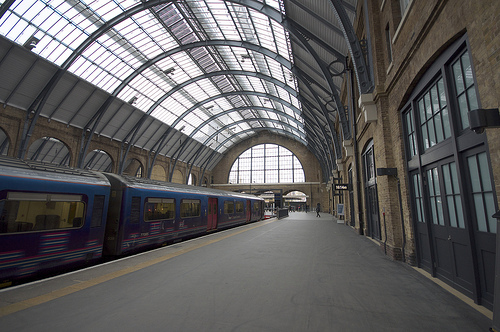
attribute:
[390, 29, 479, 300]
doors — brown